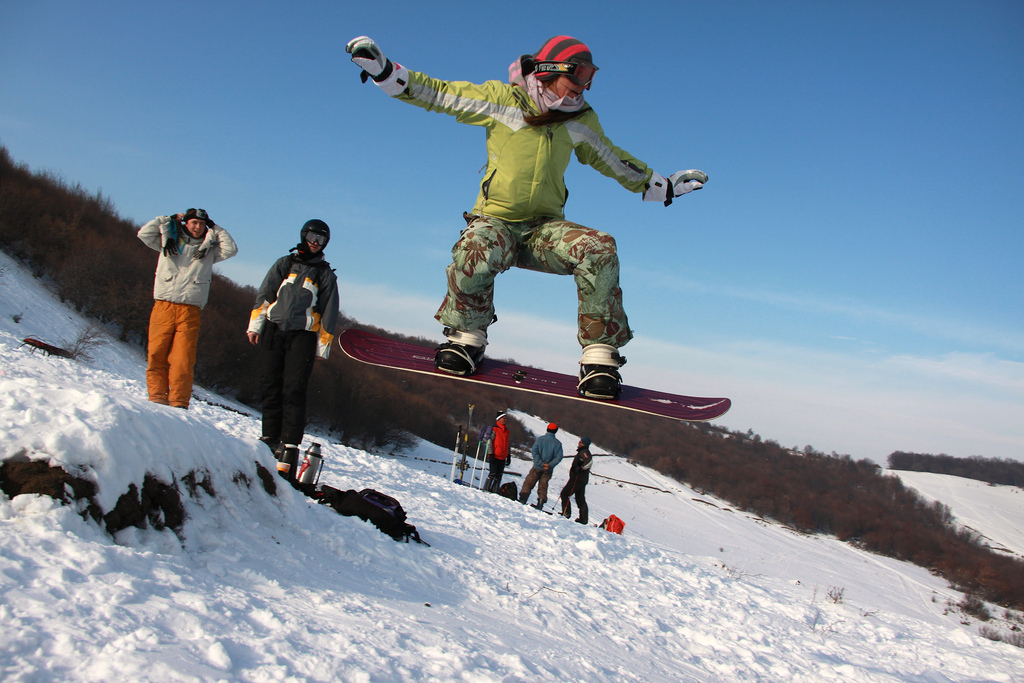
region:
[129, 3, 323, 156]
a view of sky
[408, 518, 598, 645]
a view of snow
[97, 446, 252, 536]
a view of ice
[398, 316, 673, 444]
shoes of the person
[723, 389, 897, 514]
a view of grass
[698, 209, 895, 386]
a view of clouds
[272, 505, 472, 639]
shadow on the ice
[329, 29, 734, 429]
man snowboarding in the air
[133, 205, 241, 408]
man wearing orange pants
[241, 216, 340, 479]
woman wearing black goggles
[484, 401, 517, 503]
man wearing a red winter coat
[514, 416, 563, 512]
man wearing a blue winter sweater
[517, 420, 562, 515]
man standing between two men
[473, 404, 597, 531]
three men standing on the snow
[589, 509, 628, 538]
orange bag on top of the snow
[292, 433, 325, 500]
gray, red and silver drinking mug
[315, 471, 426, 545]
black backpack beside a drinking mug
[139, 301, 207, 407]
orange snow pants on a girl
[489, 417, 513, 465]
a red jacket on a boy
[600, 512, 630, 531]
a red bag on the snow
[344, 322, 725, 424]
maroon snow board jumping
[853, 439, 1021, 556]
cearing for a ski slope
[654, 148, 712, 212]
white snow glove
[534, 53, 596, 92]
gold colored reflective goggles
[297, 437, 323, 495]
silver and black thermos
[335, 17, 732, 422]
Snowboarder in mid-air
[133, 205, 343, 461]
Two people watching the snowboarder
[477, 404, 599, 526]
Three people standing in the snow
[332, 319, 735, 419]
Maroon snowboard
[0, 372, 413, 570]
Snow-covered rock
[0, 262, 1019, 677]
Ski slopes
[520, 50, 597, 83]
Goggles on snowboarder's eyes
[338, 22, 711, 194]
Snowboarder's arms extended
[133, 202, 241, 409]
Person wearing a white jacket and orange snow pants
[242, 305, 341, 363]
Orange and white gloves on man's hands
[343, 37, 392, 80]
person has a hand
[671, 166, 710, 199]
person has a hand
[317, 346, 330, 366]
person has a hand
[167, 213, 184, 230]
person has a hand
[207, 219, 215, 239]
person has a hand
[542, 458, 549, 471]
person has a hand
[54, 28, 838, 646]
a scene during the day time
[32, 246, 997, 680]
a scene of the slopes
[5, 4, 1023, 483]
a sky with clouds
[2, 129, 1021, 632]
some trees in the background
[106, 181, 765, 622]
people standing here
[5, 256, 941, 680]
snow on the ground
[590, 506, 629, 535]
a red object on the ground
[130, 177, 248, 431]
a person standing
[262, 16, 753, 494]
a person on snowboard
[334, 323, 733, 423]
purple snowboard in the air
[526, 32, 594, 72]
red and black cap on head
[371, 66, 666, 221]
green and white jacket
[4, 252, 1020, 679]
snow on the ground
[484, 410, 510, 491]
skier in red jacket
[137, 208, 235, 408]
skier in orange pants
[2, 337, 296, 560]
small ski jump